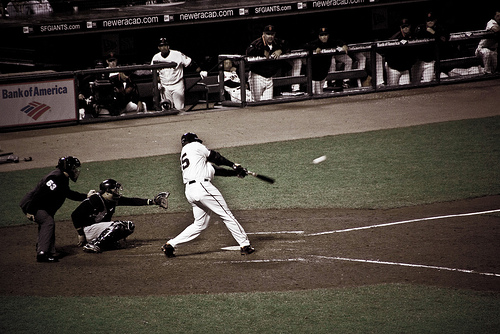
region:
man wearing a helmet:
[151, 123, 287, 283]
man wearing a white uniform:
[150, 110, 291, 277]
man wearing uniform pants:
[150, 105, 300, 280]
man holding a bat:
[160, 95, 291, 295]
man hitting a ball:
[150, 101, 385, 257]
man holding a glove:
[75, 150, 165, 255]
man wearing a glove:
[80, 160, 160, 290]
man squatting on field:
[75, 155, 170, 285]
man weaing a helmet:
[20, 115, 80, 270]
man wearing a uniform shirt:
[20, 129, 77, 276]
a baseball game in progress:
[0, 1, 495, 328]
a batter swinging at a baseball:
[160, 114, 280, 264]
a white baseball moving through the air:
[305, 148, 334, 169]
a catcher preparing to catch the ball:
[72, 172, 169, 255]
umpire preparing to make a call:
[18, 145, 96, 268]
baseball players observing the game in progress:
[94, 8, 496, 117]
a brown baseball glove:
[151, 188, 172, 212]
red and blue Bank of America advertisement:
[0, 76, 82, 127]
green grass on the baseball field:
[1, 290, 498, 331]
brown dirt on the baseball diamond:
[0, 210, 495, 288]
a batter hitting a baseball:
[159, 123, 345, 276]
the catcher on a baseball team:
[68, 173, 174, 261]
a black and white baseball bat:
[238, 162, 276, 194]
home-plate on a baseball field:
[220, 240, 248, 255]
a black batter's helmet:
[177, 128, 209, 152]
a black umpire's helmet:
[52, 151, 79, 186]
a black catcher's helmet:
[95, 175, 125, 202]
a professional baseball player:
[140, 30, 211, 115]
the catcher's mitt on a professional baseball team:
[147, 190, 173, 213]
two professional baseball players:
[66, 120, 253, 280]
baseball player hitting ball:
[161, 130, 278, 267]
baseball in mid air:
[308, 154, 345, 185]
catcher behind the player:
[76, 168, 167, 270]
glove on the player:
[153, 189, 182, 216]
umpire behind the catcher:
[33, 146, 106, 272]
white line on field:
[402, 256, 423, 277]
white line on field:
[383, 215, 413, 241]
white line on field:
[340, 251, 364, 267]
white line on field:
[466, 267, 492, 279]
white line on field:
[456, 210, 471, 222]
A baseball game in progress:
[18, 104, 338, 284]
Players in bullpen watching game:
[93, 1, 493, 108]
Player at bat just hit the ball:
[158, 113, 334, 253]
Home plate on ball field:
[216, 230, 278, 270]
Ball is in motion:
[307, 146, 338, 182]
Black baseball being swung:
[224, 153, 281, 194]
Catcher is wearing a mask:
[99, 164, 126, 209]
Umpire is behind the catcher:
[23, 146, 115, 252]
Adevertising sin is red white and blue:
[6, 72, 76, 129]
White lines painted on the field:
[310, 244, 490, 283]